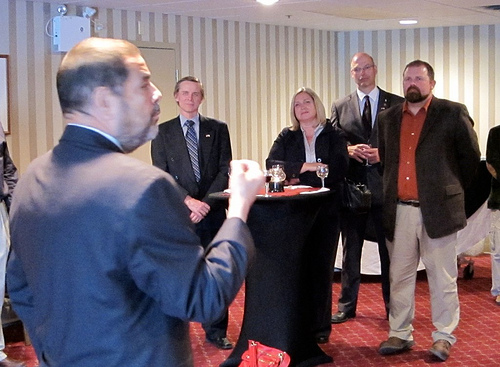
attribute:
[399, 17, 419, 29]
light — white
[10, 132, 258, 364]
suit — black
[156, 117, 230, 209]
suit — black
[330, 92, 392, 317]
suit — black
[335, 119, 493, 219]
shirt — brown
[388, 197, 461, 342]
pants — beige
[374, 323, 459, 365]
loafers — brown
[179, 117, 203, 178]
tie — striped, blue and white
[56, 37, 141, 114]
hair — gray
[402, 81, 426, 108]
beard — dark, brown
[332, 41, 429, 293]
man — bald, tall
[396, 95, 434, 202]
shirt — dress, red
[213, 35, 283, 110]
buildings — tan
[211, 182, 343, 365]
table — round, black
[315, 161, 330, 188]
glass — empty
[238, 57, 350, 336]
woman — blonde, cute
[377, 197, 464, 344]
pants — khaki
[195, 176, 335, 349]
table — black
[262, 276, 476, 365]
carpet — patterned, red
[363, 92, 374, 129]
tie — black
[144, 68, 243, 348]
person — listening, standing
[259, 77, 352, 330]
person — listening, standing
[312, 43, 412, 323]
person — listening, standing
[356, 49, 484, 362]
person — standing, listening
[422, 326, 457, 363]
shoe — brown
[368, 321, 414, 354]
shoe — brown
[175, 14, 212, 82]
stripe — white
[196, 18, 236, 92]
stripe — tan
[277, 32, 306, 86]
stripe — white